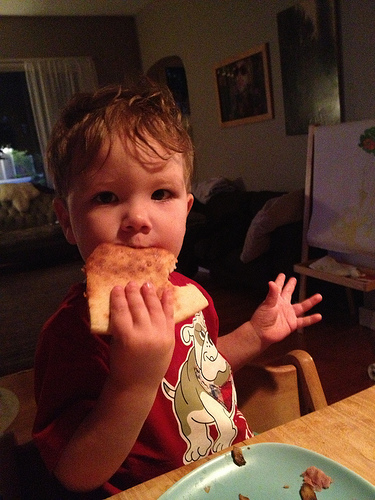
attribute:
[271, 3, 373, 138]
painting — canvas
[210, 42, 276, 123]
picture — crooked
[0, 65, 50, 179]
window — open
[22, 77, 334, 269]
boy — little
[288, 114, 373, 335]
easel — wooden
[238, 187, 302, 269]
pillow — white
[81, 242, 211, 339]
pizza — upside down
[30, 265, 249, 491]
shirt — red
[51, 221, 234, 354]
pizza — partially eaten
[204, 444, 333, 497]
meat — small 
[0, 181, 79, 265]
couch — tan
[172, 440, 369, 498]
plate — blue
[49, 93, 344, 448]
boy — little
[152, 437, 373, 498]
plate — square, green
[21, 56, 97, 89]
curtains — white